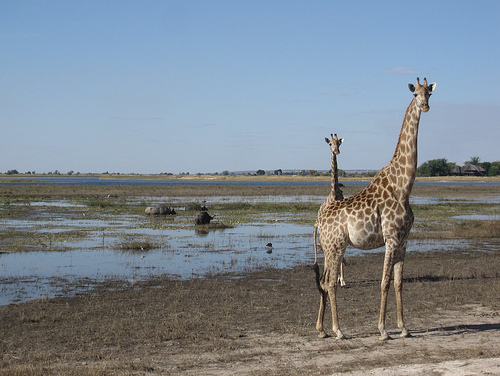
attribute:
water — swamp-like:
[0, 176, 497, 308]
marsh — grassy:
[4, 181, 499, 314]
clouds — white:
[51, 10, 389, 128]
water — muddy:
[2, 198, 453, 315]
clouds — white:
[290, 70, 499, 167]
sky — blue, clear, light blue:
[0, 0, 499, 172]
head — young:
[323, 133, 344, 168]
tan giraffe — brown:
[322, 74, 438, 350]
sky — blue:
[45, 28, 307, 112]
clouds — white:
[373, 55, 429, 78]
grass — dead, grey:
[110, 283, 237, 353]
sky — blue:
[3, 4, 498, 157]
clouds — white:
[3, 117, 126, 170]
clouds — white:
[253, 80, 381, 157]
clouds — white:
[432, 89, 499, 157]